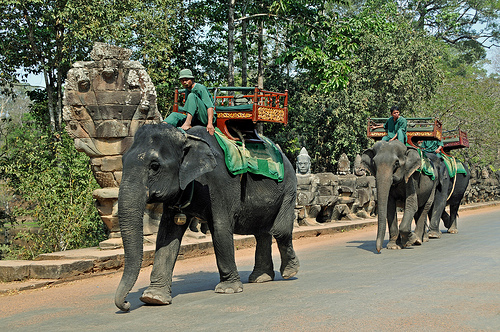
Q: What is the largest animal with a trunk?
A: Elephant.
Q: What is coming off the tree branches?
A: Leaves.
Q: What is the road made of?
A: Concrete.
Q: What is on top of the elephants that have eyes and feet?
A: Humans.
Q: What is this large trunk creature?
A: Elephant.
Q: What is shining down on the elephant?
A: Sunlight.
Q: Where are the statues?
A: Along the road.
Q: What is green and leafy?
A: Trees.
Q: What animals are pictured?
A: Elephants.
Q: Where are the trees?
A: Behind the elephants.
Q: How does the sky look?
A: Blue and clear.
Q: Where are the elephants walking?
A: On the road.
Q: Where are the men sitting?
A: On top of the elephants.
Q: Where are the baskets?
A: On top of the elephants.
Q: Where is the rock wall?
A: On the side of the road.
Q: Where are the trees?
A: Behind the statues.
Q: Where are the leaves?
A: On the trees.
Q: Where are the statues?
A: On the side of the road.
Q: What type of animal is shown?
A: Elephants.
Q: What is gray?
A: Elephants.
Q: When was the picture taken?
A: Daytime.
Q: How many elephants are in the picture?
A: Three.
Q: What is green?
A: People's outfits.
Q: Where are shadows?
A: On the ground.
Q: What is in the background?
A: Trees.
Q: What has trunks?
A: The elephants.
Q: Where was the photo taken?
A: On a street.